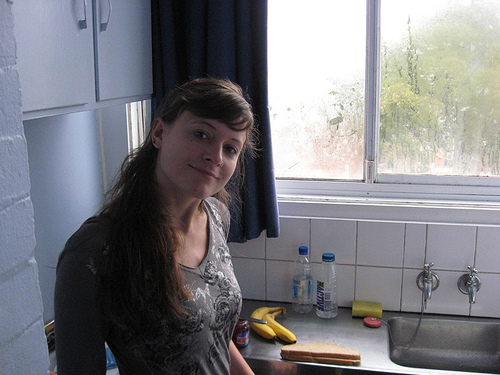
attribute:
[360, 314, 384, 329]
sink stopper — red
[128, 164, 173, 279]
hair — long, brown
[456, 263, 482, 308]
faucet — silver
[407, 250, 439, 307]
faucet — silver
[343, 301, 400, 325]
sponge — yellow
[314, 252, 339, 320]
bottle — empty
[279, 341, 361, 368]
bread — unused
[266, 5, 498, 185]
window — closed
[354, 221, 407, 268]
tile — white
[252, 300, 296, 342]
bananas — yellow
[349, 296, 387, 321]
sponge — yellow, green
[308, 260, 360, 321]
bottle — empty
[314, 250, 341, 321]
bottle — empty, plastic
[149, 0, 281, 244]
curtain — blue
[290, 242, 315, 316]
bottle — empty, plastic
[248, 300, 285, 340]
banana — yellow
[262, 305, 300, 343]
banana — yellow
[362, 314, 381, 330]
plug — red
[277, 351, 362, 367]
bread — unused